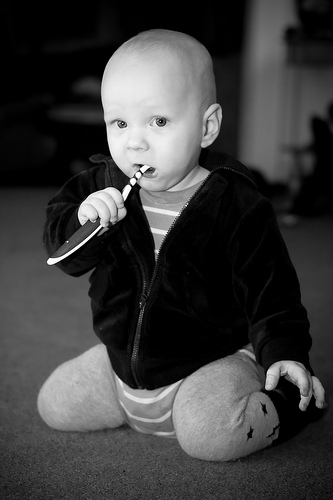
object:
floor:
[6, 258, 332, 499]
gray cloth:
[193, 380, 229, 438]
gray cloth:
[57, 368, 104, 425]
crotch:
[113, 380, 186, 438]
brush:
[46, 165, 150, 268]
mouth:
[132, 163, 157, 177]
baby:
[35, 27, 327, 462]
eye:
[150, 115, 171, 128]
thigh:
[171, 350, 327, 463]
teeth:
[149, 167, 152, 171]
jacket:
[42, 150, 314, 391]